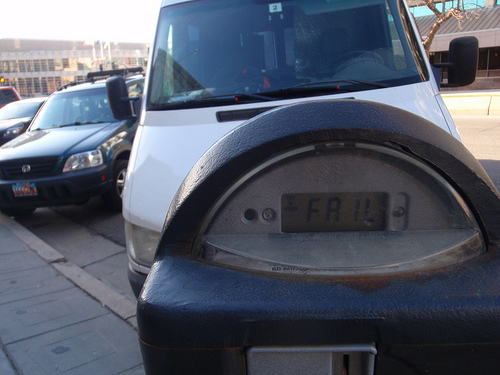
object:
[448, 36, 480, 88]
mirror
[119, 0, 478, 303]
van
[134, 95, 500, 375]
meter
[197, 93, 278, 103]
wiper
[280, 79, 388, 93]
wiper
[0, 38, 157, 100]
building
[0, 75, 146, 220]
truck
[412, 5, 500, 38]
brown roof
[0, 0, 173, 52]
sky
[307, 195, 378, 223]
letters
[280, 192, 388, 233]
timer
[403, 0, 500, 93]
building